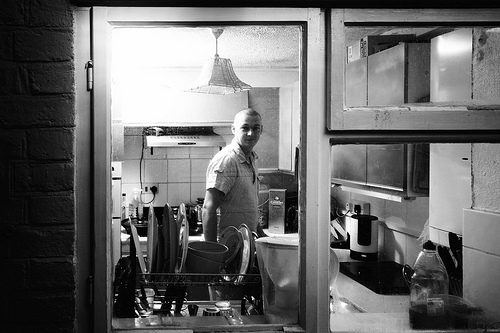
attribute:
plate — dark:
[141, 197, 196, 275]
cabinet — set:
[329, 8, 499, 140]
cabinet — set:
[306, 141, 429, 201]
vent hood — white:
[141, 124, 226, 151]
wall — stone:
[2, 0, 69, 331]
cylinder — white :
[347, 212, 383, 263]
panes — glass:
[347, 32, 395, 100]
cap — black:
[423, 240, 436, 250]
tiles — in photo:
[166, 156, 203, 200]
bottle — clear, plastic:
[407, 237, 452, 331]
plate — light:
[174, 204, 189, 277]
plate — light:
[143, 204, 160, 276]